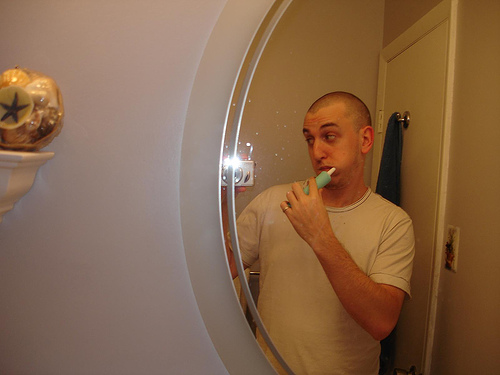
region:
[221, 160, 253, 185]
HE IS HOLDING A SILVER CAMERA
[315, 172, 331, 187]
USING A LIGHT GREEN TOOTHBRUSH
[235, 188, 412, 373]
HE IS WEARING A WHITE SHIRT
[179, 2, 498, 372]
HE IS TAKING A PICTURE IN THE MIRROR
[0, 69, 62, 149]
COLLECTION OF SHELLS ON SHELF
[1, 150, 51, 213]
WHITE SHELF SEA SHELLS ARE SITTING ON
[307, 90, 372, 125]
MAN HAS NO HAIR ON HEAD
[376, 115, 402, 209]
BLUE TOWEL HANGING ON DOOR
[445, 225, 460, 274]
LIGHT SWITCH HAS FLOWERS ON IT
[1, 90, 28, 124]
STAR PRINT ON ONE OF THE SEA SHELLS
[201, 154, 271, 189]
refelction of the camera in the mirror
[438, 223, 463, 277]
light switch by the door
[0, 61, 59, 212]
sea shells displayed on a shelf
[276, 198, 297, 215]
ring on a finger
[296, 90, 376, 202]
man brushing his teeth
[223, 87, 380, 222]
man taking a selfie while brushing his teeth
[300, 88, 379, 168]
man a a very close cut hair style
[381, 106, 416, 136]
hook on back of door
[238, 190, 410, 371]
white t-shirt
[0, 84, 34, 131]
sea shell has a star shape in it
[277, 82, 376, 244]
man brushing his teeth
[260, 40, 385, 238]
man brushing his teeth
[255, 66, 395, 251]
man brushing his teeth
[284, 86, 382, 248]
man brushing his teeth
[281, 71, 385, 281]
man brushing his teeth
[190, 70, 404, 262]
man is taking a picture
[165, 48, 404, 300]
man is taking a picture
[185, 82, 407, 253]
man is taking a picture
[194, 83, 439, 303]
man is taking a picture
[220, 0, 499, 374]
Mirror on the wall.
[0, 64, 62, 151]
glass bowl on the shelf.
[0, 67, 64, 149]
Sea shells in bowl.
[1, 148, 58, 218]
White shelf on the wall.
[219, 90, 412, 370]
Man brushing teeth.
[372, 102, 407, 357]
Robe hanging on the door.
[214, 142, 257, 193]
Silver colored camera in hand.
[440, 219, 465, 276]
Switch plate on the wall.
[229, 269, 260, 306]
White towel on rod.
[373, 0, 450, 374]
White door in the wall.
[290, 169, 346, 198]
the handle is blue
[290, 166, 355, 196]
the toothbrush is blue and white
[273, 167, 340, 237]
the hand is holding the toothbrush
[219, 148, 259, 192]
the camera is silver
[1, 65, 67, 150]
the shells are in a basket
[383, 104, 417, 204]
the towel is on a hook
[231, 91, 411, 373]
the man is taking a picture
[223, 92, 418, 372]
the man is brushing his teeth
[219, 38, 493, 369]
the mirror reflects the man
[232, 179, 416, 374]
the shirt is white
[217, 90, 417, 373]
man holding silver camera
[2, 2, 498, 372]
shiny mirror hanging on gray painted wall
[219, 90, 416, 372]
black towel hanging behind man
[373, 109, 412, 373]
black towel hanging on silver hook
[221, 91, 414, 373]
man wearing white tshirt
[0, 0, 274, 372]
porcelain decoration anchored to gray wall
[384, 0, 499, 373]
light switch on white wall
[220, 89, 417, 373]
man wearing gold ring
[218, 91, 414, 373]
man holding green and white toothbrush